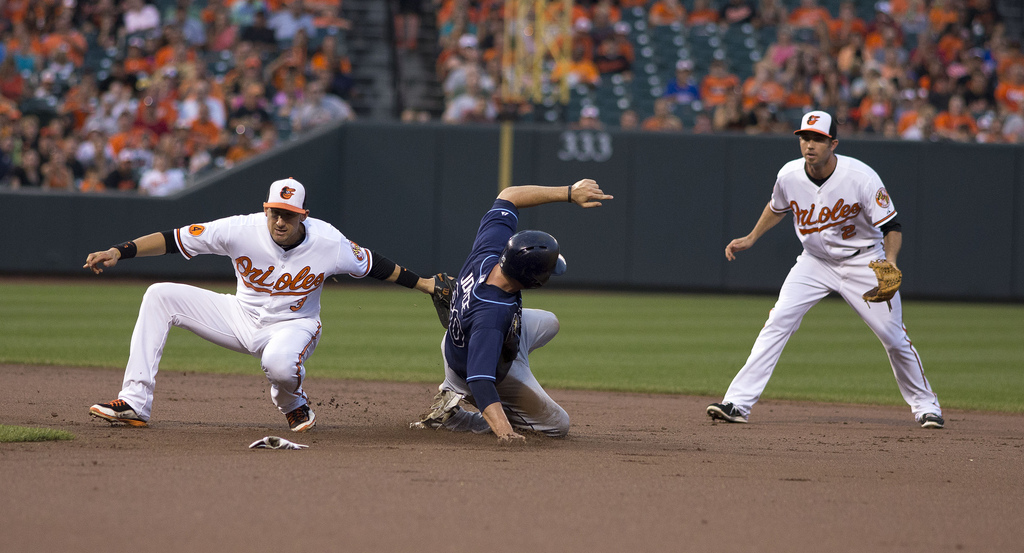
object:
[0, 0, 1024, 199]
stands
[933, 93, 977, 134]
spectator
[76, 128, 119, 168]
spectator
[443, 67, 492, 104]
spectator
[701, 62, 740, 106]
spectator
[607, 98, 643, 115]
seat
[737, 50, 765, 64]
seat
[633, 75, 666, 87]
seat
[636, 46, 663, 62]
seat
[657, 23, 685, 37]
seat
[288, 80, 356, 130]
person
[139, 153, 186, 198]
person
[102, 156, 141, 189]
person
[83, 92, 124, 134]
person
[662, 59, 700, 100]
person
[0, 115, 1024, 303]
wall